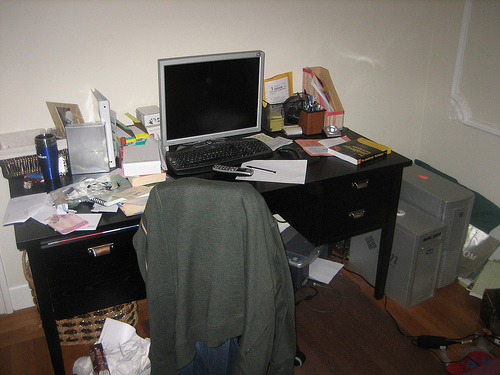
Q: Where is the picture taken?
A: Home office.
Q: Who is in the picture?
A: No one.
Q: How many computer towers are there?
A: Two.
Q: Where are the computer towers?
A: Floor.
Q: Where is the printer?
A: Under desk.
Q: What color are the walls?
A: Beige.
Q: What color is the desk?
A: Black.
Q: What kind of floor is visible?
A: Wood.